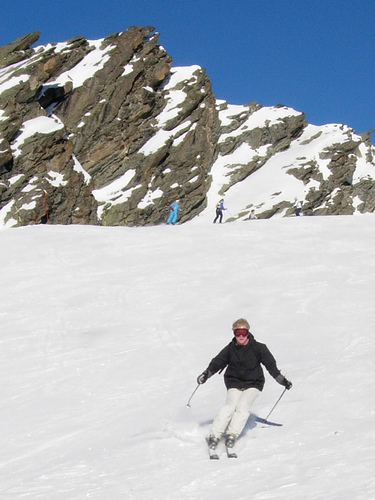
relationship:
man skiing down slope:
[197, 318, 294, 451] [3, 222, 363, 498]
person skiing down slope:
[214, 199, 228, 223] [3, 222, 363, 498]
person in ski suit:
[166, 199, 184, 225] [163, 201, 182, 222]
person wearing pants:
[204, 184, 237, 228] [213, 208, 224, 221]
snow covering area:
[2, 213, 373, 499] [2, 209, 364, 496]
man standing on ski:
[197, 318, 294, 451] [224, 439, 236, 458]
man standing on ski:
[197, 318, 294, 451] [204, 436, 217, 461]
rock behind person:
[1, 24, 221, 226] [166, 199, 184, 225]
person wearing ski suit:
[166, 196, 185, 227] [172, 200, 180, 219]